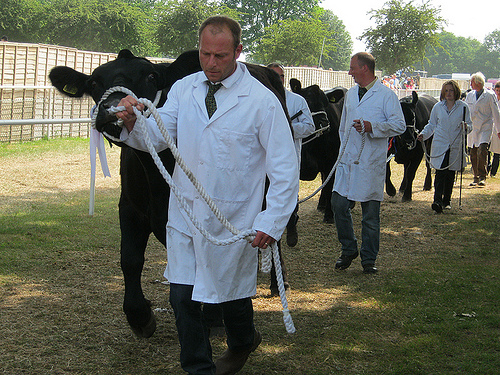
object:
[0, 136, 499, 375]
field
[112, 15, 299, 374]
field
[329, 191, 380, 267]
pants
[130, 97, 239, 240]
rope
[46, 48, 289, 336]
cow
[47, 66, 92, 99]
ear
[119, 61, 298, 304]
jacket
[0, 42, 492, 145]
fence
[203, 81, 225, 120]
tie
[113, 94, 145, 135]
hand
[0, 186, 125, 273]
grass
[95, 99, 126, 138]
nose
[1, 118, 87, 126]
rail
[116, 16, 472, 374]
line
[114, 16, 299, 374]
man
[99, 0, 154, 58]
trees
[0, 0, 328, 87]
background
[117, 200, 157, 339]
leg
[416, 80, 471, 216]
woman